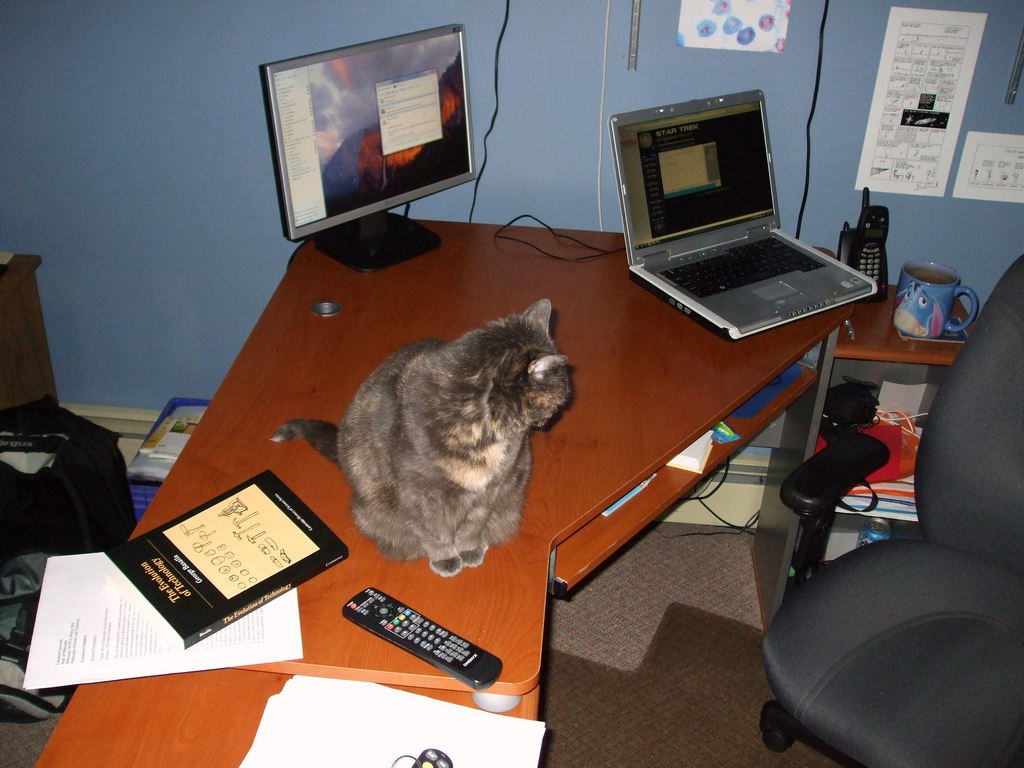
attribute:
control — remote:
[336, 568, 514, 718]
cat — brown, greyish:
[269, 285, 591, 584]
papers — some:
[12, 554, 322, 710]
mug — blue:
[883, 250, 985, 356]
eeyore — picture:
[890, 280, 951, 339]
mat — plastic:
[535, 589, 825, 764]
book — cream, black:
[159, 451, 412, 674]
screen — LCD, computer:
[245, 18, 498, 245]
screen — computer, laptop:
[614, 111, 770, 245]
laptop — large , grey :
[605, 72, 882, 347]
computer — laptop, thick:
[619, 95, 866, 346]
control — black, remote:
[331, 569, 524, 699]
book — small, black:
[117, 474, 357, 660]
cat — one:
[318, 292, 563, 574]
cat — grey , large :
[271, 299, 574, 576]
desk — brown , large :
[38, 200, 860, 764]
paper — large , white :
[23, 550, 302, 695]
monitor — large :
[258, 27, 479, 280]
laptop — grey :
[606, 88, 874, 339]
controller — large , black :
[340, 583, 501, 698]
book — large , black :
[109, 466, 345, 644]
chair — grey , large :
[759, 254, 1021, 764]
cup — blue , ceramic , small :
[893, 261, 976, 342]